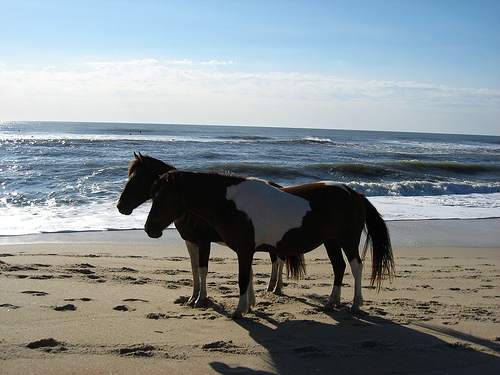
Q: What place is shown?
A: It is a beach.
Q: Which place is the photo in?
A: It is at the beach.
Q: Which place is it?
A: It is a beach.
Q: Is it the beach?
A: Yes, it is the beach.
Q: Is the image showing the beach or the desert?
A: It is showing the beach.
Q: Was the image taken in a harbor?
A: No, the picture was taken in a beach.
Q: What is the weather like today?
A: It is cloudy.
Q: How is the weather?
A: It is cloudy.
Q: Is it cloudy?
A: Yes, it is cloudy.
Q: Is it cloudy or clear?
A: It is cloudy.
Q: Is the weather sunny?
A: No, it is cloudy.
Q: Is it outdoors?
A: Yes, it is outdoors.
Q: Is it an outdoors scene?
A: Yes, it is outdoors.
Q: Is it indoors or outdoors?
A: It is outdoors.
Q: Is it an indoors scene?
A: No, it is outdoors.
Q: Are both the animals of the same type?
A: Yes, all the animals are horses.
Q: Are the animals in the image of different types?
A: No, all the animals are horses.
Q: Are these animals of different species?
A: No, all the animals are horses.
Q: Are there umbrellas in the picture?
A: No, there are no umbrellas.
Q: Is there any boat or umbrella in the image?
A: No, there are no umbrellas or boats.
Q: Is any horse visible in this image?
A: Yes, there is a horse.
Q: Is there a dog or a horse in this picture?
A: Yes, there is a horse.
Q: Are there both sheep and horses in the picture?
A: No, there is a horse but no sheep.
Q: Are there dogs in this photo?
A: No, there are no dogs.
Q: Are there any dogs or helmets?
A: No, there are no dogs or helmets.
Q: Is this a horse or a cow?
A: This is a horse.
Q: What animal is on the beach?
A: The horse is on the beach.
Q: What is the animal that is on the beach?
A: The animal is a horse.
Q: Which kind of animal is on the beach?
A: The animal is a horse.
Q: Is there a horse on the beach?
A: Yes, there is a horse on the beach.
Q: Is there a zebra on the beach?
A: No, there is a horse on the beach.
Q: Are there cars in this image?
A: No, there are no cars.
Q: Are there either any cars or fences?
A: No, there are no cars or fences.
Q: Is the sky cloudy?
A: Yes, the sky is cloudy.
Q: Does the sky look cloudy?
A: Yes, the sky is cloudy.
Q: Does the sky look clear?
A: No, the sky is cloudy.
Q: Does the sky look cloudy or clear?
A: The sky is cloudy.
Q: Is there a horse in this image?
A: Yes, there is a horse.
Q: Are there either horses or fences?
A: Yes, there is a horse.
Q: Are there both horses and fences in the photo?
A: No, there is a horse but no fences.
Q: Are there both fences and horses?
A: No, there is a horse but no fences.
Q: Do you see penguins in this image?
A: No, there are no penguins.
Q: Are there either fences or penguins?
A: No, there are no penguins or fences.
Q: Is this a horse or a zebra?
A: This is a horse.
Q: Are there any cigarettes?
A: No, there are no cigarettes.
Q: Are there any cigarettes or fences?
A: No, there are no cigarettes or fences.